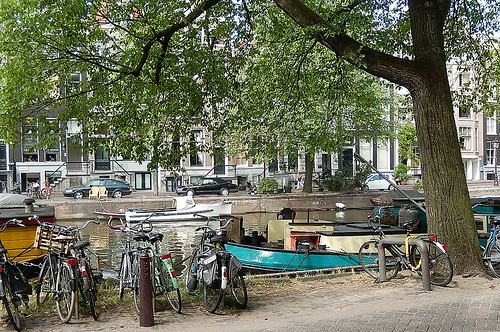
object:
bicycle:
[477, 219, 500, 281]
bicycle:
[357, 205, 454, 287]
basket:
[32, 222, 70, 254]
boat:
[223, 240, 359, 274]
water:
[33, 198, 371, 278]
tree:
[0, 0, 499, 279]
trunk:
[272, 1, 498, 283]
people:
[44, 171, 52, 201]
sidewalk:
[8, 283, 498, 331]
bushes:
[314, 171, 376, 194]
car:
[358, 172, 399, 194]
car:
[176, 175, 240, 197]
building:
[392, 62, 499, 184]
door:
[214, 146, 228, 176]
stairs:
[52, 180, 58, 188]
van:
[60, 177, 133, 200]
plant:
[253, 176, 286, 194]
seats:
[85, 187, 111, 201]